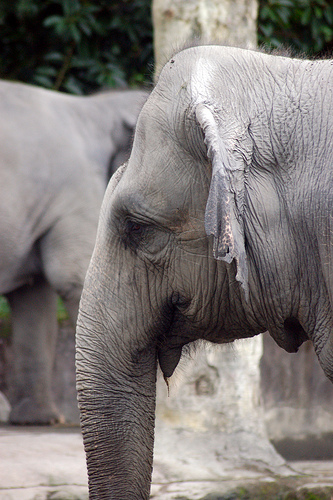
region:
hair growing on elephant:
[240, 28, 321, 80]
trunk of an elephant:
[61, 255, 200, 498]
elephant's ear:
[180, 87, 281, 303]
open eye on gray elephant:
[119, 205, 185, 259]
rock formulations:
[215, 384, 300, 478]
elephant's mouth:
[137, 285, 219, 382]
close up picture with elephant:
[3, 26, 327, 491]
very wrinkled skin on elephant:
[256, 62, 324, 159]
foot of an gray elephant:
[9, 249, 64, 429]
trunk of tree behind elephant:
[71, 0, 268, 491]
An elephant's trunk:
[74, 377, 155, 498]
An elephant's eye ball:
[119, 213, 152, 239]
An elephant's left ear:
[195, 105, 264, 305]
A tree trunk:
[147, 1, 275, 49]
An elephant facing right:
[1, 79, 77, 433]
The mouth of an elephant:
[138, 299, 199, 390]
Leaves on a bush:
[20, 1, 160, 97]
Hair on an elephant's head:
[132, 29, 291, 79]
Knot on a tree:
[181, 364, 241, 410]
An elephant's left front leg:
[8, 293, 64, 426]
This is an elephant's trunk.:
[59, 247, 170, 498]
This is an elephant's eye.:
[116, 183, 186, 269]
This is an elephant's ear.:
[178, 112, 295, 314]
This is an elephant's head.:
[36, 38, 330, 488]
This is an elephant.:
[0, 62, 195, 428]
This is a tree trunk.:
[191, 385, 269, 453]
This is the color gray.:
[97, 310, 136, 348]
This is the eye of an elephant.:
[112, 207, 170, 291]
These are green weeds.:
[205, 456, 332, 498]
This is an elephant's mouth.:
[130, 331, 232, 406]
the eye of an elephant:
[116, 213, 149, 244]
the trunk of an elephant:
[93, 361, 155, 496]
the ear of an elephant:
[179, 93, 275, 269]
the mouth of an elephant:
[142, 305, 195, 387]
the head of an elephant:
[103, 53, 272, 337]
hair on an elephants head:
[151, 30, 215, 65]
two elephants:
[4, 68, 297, 317]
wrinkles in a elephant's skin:
[82, 294, 130, 361]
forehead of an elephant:
[131, 116, 183, 179]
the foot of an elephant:
[6, 397, 66, 441]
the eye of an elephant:
[129, 220, 143, 235]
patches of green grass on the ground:
[231, 473, 331, 497]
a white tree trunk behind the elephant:
[151, 0, 292, 482]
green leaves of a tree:
[1, 1, 332, 95]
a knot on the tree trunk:
[194, 372, 217, 400]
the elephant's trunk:
[73, 246, 161, 498]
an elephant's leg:
[4, 278, 67, 425]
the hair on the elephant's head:
[160, 33, 332, 57]